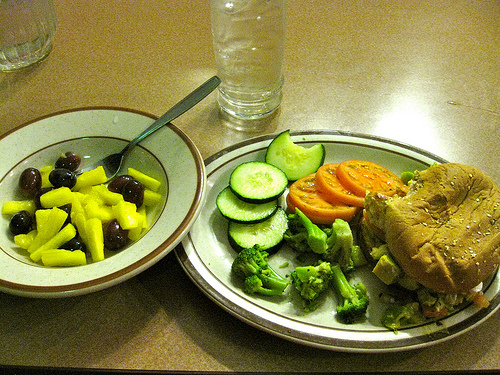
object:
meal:
[53, 150, 81, 171]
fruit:
[8, 209, 34, 235]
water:
[209, 0, 286, 121]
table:
[0, 0, 500, 375]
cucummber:
[264, 128, 326, 181]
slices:
[225, 204, 290, 256]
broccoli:
[229, 246, 290, 298]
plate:
[171, 126, 500, 356]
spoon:
[72, 74, 222, 196]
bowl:
[0, 104, 208, 300]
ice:
[256, 15, 261, 21]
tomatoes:
[314, 162, 367, 207]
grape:
[48, 168, 77, 189]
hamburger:
[359, 162, 500, 296]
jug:
[0, 0, 57, 74]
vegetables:
[329, 262, 371, 325]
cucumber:
[228, 160, 289, 205]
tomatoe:
[335, 158, 404, 198]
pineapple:
[71, 166, 107, 191]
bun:
[383, 160, 500, 295]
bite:
[384, 169, 422, 201]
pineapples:
[125, 167, 160, 193]